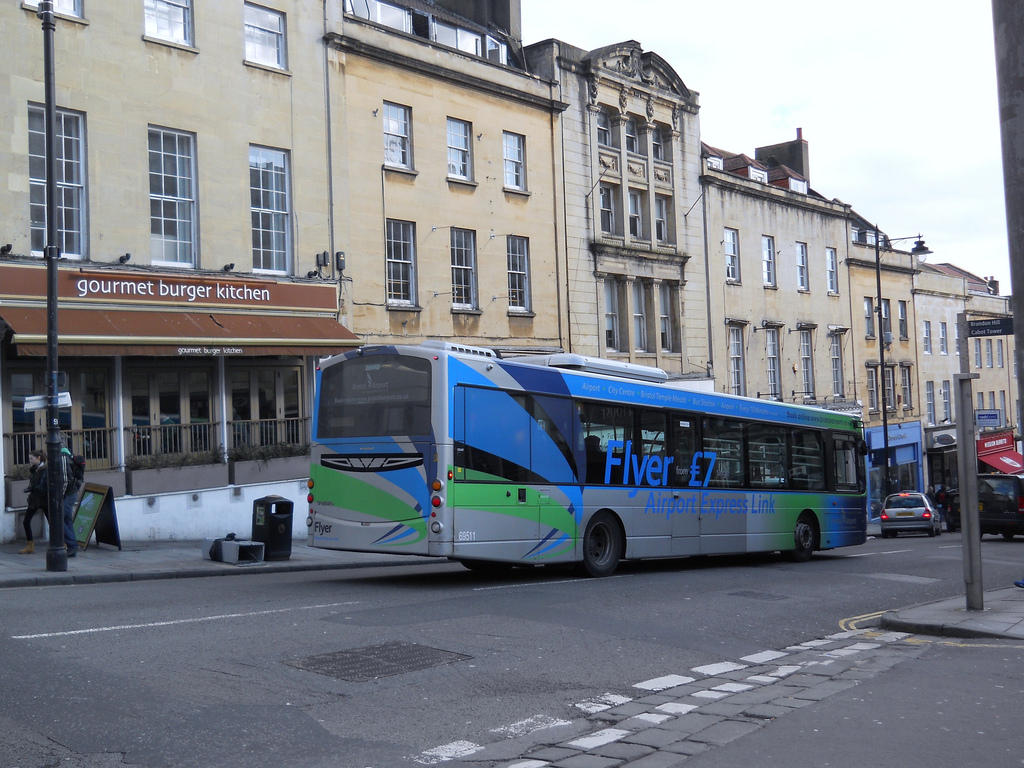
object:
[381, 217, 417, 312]
window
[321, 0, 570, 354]
building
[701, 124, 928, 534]
building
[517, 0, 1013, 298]
sky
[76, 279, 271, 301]
sign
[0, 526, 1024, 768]
street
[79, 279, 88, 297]
letter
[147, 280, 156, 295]
letter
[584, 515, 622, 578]
tire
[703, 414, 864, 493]
windshield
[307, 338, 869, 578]
bus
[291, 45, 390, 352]
wall